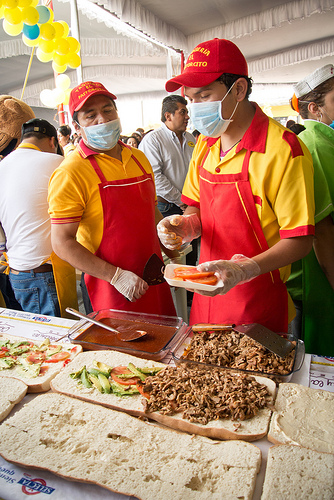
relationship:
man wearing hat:
[167, 44, 316, 326] [161, 34, 260, 86]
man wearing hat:
[29, 75, 169, 317] [69, 77, 119, 115]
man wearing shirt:
[167, 44, 316, 326] [169, 117, 320, 320]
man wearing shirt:
[29, 75, 169, 317] [53, 146, 159, 272]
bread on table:
[1, 336, 334, 500] [3, 307, 334, 499]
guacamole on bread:
[23, 410, 210, 495] [1, 336, 334, 500]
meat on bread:
[153, 362, 262, 431] [1, 336, 334, 500]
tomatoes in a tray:
[174, 267, 215, 283] [159, 260, 227, 296]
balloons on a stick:
[3, 0, 85, 79] [16, 49, 41, 109]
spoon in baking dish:
[64, 307, 148, 343] [64, 306, 185, 359]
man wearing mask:
[167, 44, 316, 326] [187, 86, 249, 146]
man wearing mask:
[29, 75, 169, 317] [78, 117, 129, 151]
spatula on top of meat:
[188, 318, 290, 358] [182, 324, 292, 371]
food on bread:
[4, 334, 267, 426] [1, 336, 334, 500]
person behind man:
[0, 117, 66, 318] [156, 36, 316, 335]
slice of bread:
[6, 395, 246, 500] [1, 336, 334, 500]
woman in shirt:
[282, 69, 333, 346] [298, 123, 334, 298]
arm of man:
[226, 231, 311, 273] [167, 44, 316, 326]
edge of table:
[3, 304, 330, 375] [3, 307, 334, 499]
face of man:
[187, 86, 249, 146] [167, 44, 316, 326]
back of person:
[3, 123, 71, 322] [4, 153, 68, 265]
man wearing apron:
[167, 44, 316, 326] [196, 135, 294, 324]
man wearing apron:
[29, 75, 169, 317] [80, 145, 174, 316]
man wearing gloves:
[167, 44, 316, 326] [161, 212, 249, 301]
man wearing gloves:
[29, 75, 169, 317] [108, 267, 150, 300]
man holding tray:
[167, 44, 316, 326] [159, 260, 227, 296]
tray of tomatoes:
[159, 260, 227, 296] [174, 267, 215, 283]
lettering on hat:
[180, 49, 216, 72] [161, 34, 260, 86]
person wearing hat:
[4, 153, 68, 265] [19, 120, 64, 153]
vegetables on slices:
[7, 336, 149, 398] [1, 337, 159, 414]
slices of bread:
[1, 337, 159, 414] [1, 336, 334, 500]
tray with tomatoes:
[159, 260, 227, 296] [174, 267, 215, 283]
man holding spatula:
[29, 75, 169, 317] [134, 249, 169, 289]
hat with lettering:
[161, 34, 260, 86] [180, 49, 216, 72]